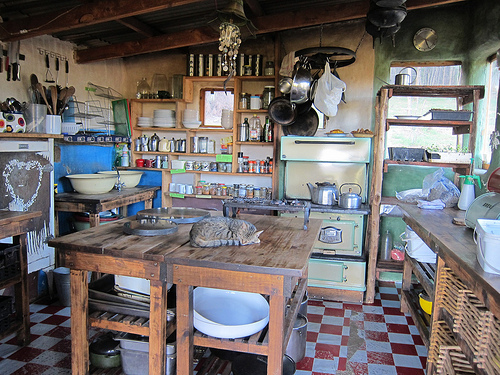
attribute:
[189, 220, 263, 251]
cat — sleeping, gray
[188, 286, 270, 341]
bowl — large, white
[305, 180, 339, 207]
kettle — silver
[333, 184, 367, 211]
kettle — silver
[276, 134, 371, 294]
stove — green, antique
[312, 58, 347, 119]
bag — white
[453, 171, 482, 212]
bottle — green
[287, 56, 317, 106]
pot — metal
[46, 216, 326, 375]
table — wooden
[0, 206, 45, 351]
table — wooden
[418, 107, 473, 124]
pan — metal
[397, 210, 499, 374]
counter — wooden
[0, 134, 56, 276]
cabinet — white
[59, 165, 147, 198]
bowls — large, big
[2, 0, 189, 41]
beam — wooden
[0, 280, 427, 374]
floor — red, white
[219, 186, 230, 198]
jar — small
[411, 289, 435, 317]
bowl — yellow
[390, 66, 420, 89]
kettle — silver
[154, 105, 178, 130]
plates — white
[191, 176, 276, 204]
jars — glass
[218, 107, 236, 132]
bowls — white